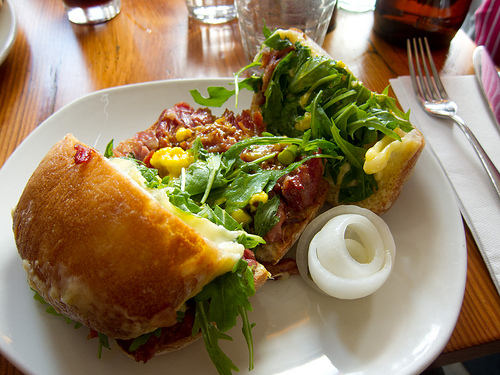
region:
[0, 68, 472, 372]
THIS IS A WHITE PLATE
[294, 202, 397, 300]
THIS IS A WHITE ONION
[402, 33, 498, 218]
THIS IS A FORK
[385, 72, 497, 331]
THIS IS A WHITE NAPKIN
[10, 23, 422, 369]
THIS IS A SANDWICH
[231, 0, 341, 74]
THIS IS A GLASS OF WATER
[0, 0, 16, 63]
THIS IS A PLATE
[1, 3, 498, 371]
THIS IS A WOOD TABLE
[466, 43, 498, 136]
THIS IS A SILVER KNIFE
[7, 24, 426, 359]
A SANDWICH CUT IN HALF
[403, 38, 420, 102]
silver tong of fork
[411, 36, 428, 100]
silver tong of fork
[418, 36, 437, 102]
silver tong of fork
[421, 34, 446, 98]
silver tong of fork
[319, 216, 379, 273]
sliced white colored onion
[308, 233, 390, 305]
sliced white colored onion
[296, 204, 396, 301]
sliced white colored onion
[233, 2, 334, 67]
clear glass on table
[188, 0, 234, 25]
clear glass on table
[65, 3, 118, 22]
clear glass on table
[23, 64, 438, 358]
white plate holding a large sandwich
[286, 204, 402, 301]
pickled onions next to the sandwich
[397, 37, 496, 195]
silver fork on top of a napkin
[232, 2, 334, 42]
clear glass full of ice water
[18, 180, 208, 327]
brown crusty bread of the sandwich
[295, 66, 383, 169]
lots of leafy lettuce on the sandwich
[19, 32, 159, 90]
brown wooden table of the restaurant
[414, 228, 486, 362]
edge of the white plate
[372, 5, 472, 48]
brown container holding a beverage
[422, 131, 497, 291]
white napkin next to the plate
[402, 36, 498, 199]
a fork on a napkin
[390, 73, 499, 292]
a white napkin under a fork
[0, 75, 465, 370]
an oval white plate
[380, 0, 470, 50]
a brown pitcher on a table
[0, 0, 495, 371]
a golden brown wood table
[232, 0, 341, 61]
a pitcher of water on a table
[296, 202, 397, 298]
rings of onion on a plate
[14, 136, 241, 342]
the top of a sandwich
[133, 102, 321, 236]
red meat on a sandwich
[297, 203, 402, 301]
a sliced piece of food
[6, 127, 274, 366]
half of a sandwich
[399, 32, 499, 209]
a silver dinner fork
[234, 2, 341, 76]
a clear empty glass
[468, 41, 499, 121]
a butter knife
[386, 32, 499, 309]
silverware on top of a white napkin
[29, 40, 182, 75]
a wooden table top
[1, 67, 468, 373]
a white plate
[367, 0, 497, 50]
a glass that is full of liquid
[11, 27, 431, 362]
a sandwich is torn open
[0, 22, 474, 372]
A meal on a plate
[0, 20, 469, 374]
food on a plate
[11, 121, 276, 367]
half of a burger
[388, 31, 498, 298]
A fork on a napkin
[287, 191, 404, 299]
onion rings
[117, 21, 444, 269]
vegetables, bread, and sauce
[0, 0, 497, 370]
plate of food on a table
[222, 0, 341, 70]
An empty drink glass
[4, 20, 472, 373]
a plate of food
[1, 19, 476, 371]
A meal served a white plate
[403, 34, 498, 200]
fork placed at side of plate